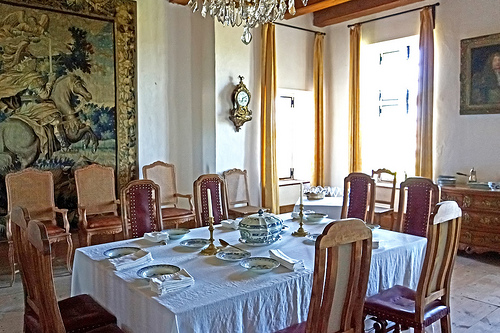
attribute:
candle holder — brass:
[201, 216, 221, 253]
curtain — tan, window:
[271, 26, 316, 92]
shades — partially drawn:
[341, 8, 443, 195]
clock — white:
[228, 75, 252, 131]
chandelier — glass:
[189, 2, 324, 39]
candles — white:
[188, 172, 303, 229]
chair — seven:
[280, 219, 374, 331]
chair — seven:
[390, 177, 440, 236]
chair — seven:
[339, 171, 375, 222]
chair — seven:
[10, 207, 117, 330]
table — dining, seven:
[58, 212, 436, 331]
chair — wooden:
[3, 166, 73, 286]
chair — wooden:
[72, 162, 129, 246]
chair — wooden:
[140, 157, 194, 228]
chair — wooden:
[221, 167, 266, 217]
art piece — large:
[2, 0, 144, 229]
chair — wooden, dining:
[294, 216, 381, 331]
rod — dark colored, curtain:
[350, 8, 425, 30]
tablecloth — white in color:
[73, 215, 434, 332]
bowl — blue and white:
[141, 255, 191, 295]